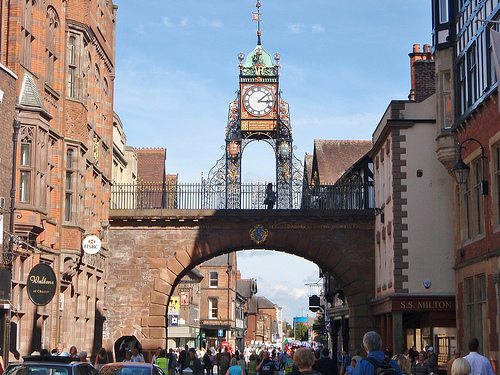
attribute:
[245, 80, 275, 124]
clock — face, white, large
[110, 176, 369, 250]
bridge — brown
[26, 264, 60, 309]
sign — hanging, business, black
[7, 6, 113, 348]
building — brick, old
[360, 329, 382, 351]
hair — gray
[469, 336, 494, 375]
man — back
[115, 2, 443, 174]
sky — clear, blue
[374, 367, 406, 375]
bag — black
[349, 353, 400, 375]
shirt — blue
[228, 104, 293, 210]
archway — brown